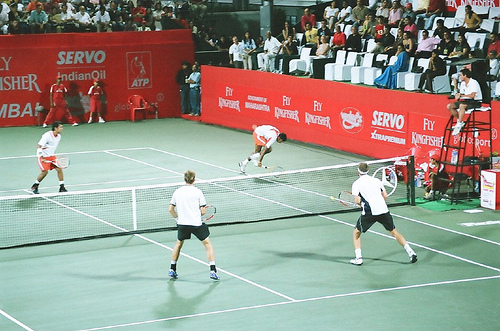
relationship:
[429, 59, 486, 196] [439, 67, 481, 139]
seat in referee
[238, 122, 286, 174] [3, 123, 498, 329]
player stumbling across tennis court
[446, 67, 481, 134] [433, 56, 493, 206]
judge sitting on a chair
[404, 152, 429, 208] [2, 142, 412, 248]
post of tennis net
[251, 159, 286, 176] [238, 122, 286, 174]
racket in a player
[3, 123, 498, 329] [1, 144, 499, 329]
tennis court with white lines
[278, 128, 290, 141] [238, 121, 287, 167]
hair on man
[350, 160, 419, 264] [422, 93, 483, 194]
man refereeing on a high seat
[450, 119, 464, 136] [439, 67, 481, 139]
shoe on referee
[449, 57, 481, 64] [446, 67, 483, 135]
green canopy over referee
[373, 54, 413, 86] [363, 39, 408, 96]
blue blanket over woman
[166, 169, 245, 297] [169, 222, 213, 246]
man wearing shorts